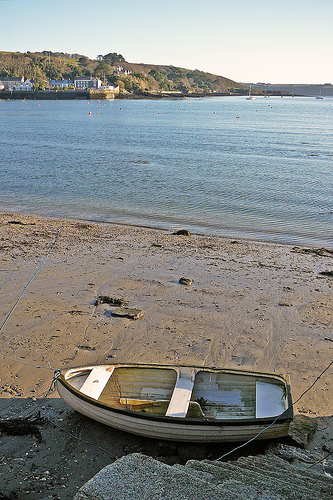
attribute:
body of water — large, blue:
[1, 98, 333, 236]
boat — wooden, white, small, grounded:
[52, 362, 296, 445]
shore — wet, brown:
[0, 210, 333, 446]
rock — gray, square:
[109, 304, 144, 320]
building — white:
[19, 79, 36, 91]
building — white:
[2, 77, 24, 92]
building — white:
[50, 76, 75, 91]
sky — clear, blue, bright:
[1, 1, 330, 54]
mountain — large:
[0, 51, 236, 89]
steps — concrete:
[69, 447, 333, 500]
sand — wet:
[169, 301, 300, 358]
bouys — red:
[11, 98, 328, 124]